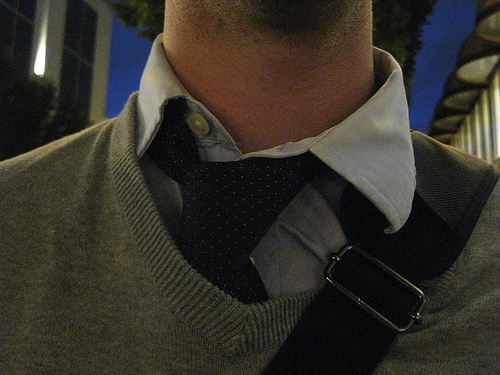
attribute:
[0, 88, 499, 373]
sweater — grey, v-neck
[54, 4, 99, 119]
window — large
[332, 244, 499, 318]
attachment — black, metal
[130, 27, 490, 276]
shirt — white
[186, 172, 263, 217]
pattern — polka dot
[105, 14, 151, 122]
sky — clear, blue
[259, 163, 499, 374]
strap — black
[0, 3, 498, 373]
male — white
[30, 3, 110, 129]
frame — white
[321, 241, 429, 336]
clasp — silver, metal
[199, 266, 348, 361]
collar — V-neck